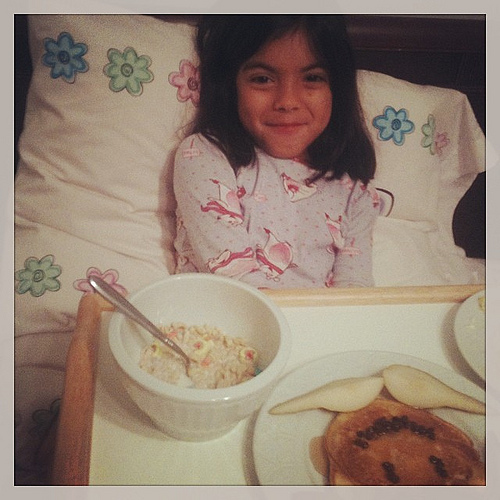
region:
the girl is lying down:
[130, 42, 470, 357]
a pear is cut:
[292, 353, 468, 443]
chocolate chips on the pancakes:
[334, 403, 422, 484]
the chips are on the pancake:
[335, 413, 464, 483]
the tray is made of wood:
[57, 390, 167, 478]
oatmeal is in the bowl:
[99, 284, 296, 494]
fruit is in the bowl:
[132, 309, 312, 449]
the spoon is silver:
[84, 255, 238, 423]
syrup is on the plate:
[290, 429, 357, 489]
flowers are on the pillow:
[13, 229, 176, 339]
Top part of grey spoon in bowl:
[90, 276, 197, 357]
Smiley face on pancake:
[348, 413, 459, 483]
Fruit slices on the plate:
[265, 360, 499, 414]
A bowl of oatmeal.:
[86, 271, 290, 446]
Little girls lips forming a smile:
[264, 116, 313, 140]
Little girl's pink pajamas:
[172, 134, 378, 286]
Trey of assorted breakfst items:
[56, 273, 491, 485]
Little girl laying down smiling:
[166, 14, 387, 288]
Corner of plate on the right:
[454, 285, 486, 385]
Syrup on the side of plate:
[305, 434, 328, 479]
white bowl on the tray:
[82, 263, 279, 433]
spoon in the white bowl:
[82, 274, 216, 381]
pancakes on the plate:
[325, 403, 475, 488]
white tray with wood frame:
[60, 292, 485, 485]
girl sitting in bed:
[182, 19, 376, 285]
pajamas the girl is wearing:
[177, 129, 377, 286]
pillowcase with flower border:
[19, 16, 478, 358]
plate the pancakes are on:
[255, 348, 487, 488]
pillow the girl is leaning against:
[23, 19, 445, 289]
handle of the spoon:
[87, 273, 165, 340]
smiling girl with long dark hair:
[170, 11, 378, 286]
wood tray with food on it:
[55, 285, 485, 485]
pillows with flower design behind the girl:
[17, 12, 482, 253]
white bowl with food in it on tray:
[106, 270, 291, 440]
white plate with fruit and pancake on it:
[250, 345, 485, 485]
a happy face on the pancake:
[320, 395, 480, 480]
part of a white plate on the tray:
[450, 285, 480, 375]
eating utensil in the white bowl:
[85, 272, 195, 372]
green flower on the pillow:
[100, 45, 151, 95]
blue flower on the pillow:
[371, 102, 416, 143]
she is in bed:
[155, 18, 435, 300]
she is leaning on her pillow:
[165, 20, 387, 294]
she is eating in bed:
[110, 14, 495, 491]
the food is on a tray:
[57, 280, 498, 486]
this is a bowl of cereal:
[82, 259, 299, 446]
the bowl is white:
[98, 258, 289, 453]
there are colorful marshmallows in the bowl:
[193, 338, 208, 355]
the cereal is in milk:
[140, 315, 268, 396]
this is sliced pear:
[266, 359, 496, 414]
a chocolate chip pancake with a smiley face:
[325, 398, 489, 488]